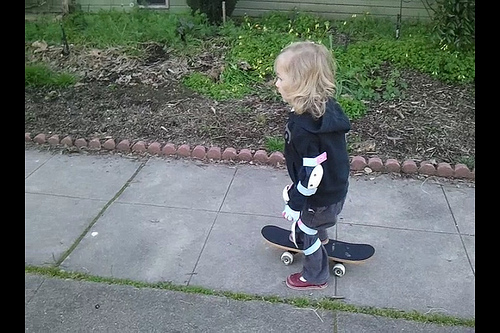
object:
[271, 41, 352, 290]
girl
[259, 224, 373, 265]
skateboard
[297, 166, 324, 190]
elbow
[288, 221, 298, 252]
knee pad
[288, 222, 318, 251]
knee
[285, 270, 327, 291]
shoe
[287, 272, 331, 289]
foot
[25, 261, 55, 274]
grass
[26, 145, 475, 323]
sidewalk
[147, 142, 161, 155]
landscaping brick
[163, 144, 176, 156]
landscaping brick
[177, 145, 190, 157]
landscaping brick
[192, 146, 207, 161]
landscaping brick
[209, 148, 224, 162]
landscaping brick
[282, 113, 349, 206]
jacket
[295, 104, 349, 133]
hood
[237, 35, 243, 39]
flower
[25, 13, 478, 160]
yard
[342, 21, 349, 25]
flower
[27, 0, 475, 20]
house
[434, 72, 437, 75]
flower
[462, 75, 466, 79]
flower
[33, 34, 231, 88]
clump of leaves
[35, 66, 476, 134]
dirt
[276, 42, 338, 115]
hair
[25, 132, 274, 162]
brick trim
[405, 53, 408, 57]
flower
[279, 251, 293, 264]
front wheel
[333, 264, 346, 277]
back wheel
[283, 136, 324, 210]
arm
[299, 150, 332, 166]
strap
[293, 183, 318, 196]
strap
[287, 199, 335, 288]
left leg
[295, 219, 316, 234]
strap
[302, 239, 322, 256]
strap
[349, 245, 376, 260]
back part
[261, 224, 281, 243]
front part